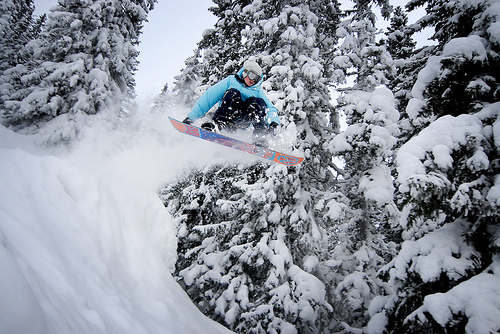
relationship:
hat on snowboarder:
[241, 60, 265, 78] [181, 59, 281, 152]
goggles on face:
[246, 70, 259, 83] [242, 68, 262, 88]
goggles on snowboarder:
[246, 70, 259, 83] [181, 59, 281, 152]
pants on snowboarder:
[214, 88, 269, 145] [181, 59, 281, 152]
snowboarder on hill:
[181, 59, 281, 152] [1, 123, 236, 333]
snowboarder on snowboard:
[181, 59, 281, 152] [167, 114, 304, 168]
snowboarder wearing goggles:
[181, 59, 281, 152] [246, 70, 259, 83]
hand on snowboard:
[180, 116, 194, 127] [167, 114, 304, 168]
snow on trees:
[1, 0, 499, 334] [1, 1, 499, 333]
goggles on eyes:
[246, 70, 259, 83] [249, 75, 258, 81]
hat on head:
[241, 60, 265, 78] [240, 59, 263, 89]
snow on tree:
[1, 0, 499, 334] [383, 1, 498, 333]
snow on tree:
[1, 0, 499, 334] [328, 0, 391, 332]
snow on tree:
[1, 0, 499, 334] [372, 4, 428, 126]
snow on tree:
[1, 0, 499, 334] [160, 0, 332, 333]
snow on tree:
[1, 0, 499, 334] [1, 1, 159, 149]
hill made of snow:
[1, 123, 236, 333] [1, 0, 499, 334]